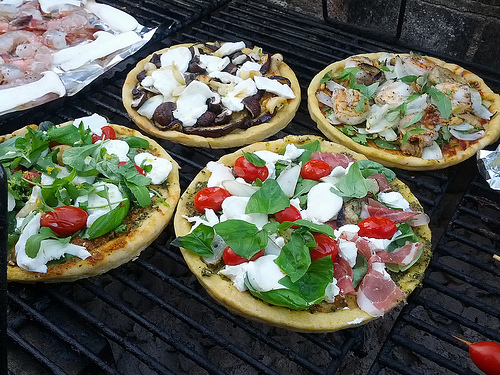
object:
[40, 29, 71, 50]
shrimp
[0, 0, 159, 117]
tin foil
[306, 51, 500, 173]
pizza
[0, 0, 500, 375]
grill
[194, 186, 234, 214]
tomato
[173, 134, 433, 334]
pizza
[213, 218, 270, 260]
basil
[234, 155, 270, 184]
tomato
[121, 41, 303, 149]
pizza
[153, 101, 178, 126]
mushroom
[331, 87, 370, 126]
shrimp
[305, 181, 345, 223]
mozzarella cheese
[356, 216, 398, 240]
tomato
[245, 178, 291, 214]
basil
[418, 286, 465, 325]
coal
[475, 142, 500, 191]
foil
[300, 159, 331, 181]
tomato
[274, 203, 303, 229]
tomato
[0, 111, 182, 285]
pizza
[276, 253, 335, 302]
vegetable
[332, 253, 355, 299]
meat